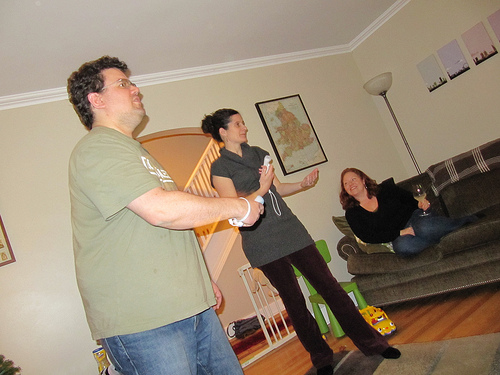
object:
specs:
[98, 78, 137, 89]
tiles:
[368, 290, 500, 343]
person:
[200, 108, 405, 374]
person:
[339, 167, 457, 257]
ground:
[410, 300, 499, 337]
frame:
[253, 93, 327, 177]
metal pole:
[376, 91, 428, 173]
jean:
[98, 304, 248, 375]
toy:
[358, 305, 397, 336]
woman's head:
[200, 106, 249, 144]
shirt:
[343, 189, 415, 244]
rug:
[300, 330, 497, 375]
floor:
[227, 285, 499, 375]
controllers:
[263, 155, 272, 174]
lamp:
[359, 71, 437, 176]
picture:
[255, 94, 326, 173]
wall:
[0, 0, 497, 371]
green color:
[67, 124, 218, 343]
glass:
[410, 181, 431, 217]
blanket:
[415, 133, 499, 190]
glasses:
[99, 78, 135, 91]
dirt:
[429, 347, 468, 372]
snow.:
[396, 308, 469, 348]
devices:
[260, 155, 272, 174]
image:
[0, 0, 499, 375]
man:
[64, 55, 266, 375]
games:
[262, 154, 273, 175]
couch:
[342, 135, 500, 309]